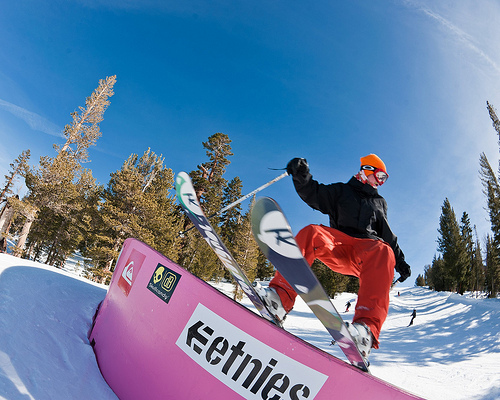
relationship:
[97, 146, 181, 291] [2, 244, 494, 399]
tree in a field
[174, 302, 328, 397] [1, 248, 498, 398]
advertising on slope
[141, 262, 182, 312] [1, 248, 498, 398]
advertising on slope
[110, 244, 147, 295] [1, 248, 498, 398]
advertising on slope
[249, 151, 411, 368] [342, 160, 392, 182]
skier wearing goggles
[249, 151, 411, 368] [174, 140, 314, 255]
skier holding ski pole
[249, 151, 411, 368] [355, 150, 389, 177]
skier has hat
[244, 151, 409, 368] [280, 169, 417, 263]
skier has jacket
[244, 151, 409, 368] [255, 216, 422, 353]
skier has pants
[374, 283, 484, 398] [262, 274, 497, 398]
snow on ground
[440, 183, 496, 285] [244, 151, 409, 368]
pinetrees behind skier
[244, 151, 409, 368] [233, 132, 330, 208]
skier has gloves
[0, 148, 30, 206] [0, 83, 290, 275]
tree in field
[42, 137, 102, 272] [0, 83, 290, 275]
tree in field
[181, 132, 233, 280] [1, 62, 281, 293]
tree in field